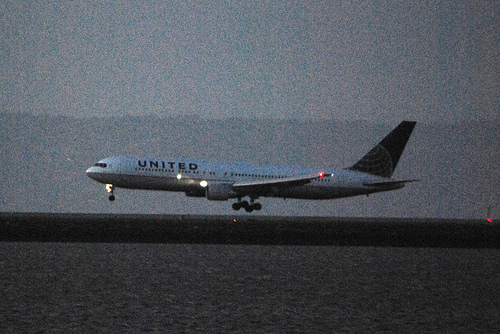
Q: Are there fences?
A: No, there are no fences.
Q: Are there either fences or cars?
A: No, there are no fences or cars.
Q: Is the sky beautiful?
A: Yes, the sky is beautiful.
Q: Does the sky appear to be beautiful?
A: Yes, the sky is beautiful.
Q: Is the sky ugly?
A: No, the sky is beautiful.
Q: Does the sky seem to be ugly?
A: No, the sky is beautiful.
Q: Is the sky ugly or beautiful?
A: The sky is beautiful.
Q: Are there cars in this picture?
A: No, there are no cars.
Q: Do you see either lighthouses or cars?
A: No, there are no cars or lighthouses.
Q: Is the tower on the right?
A: Yes, the tower is on the right of the image.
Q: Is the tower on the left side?
A: No, the tower is on the right of the image.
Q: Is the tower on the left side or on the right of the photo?
A: The tower is on the right of the image.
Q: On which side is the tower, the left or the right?
A: The tower is on the right of the image.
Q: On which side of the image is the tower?
A: The tower is on the right of the image.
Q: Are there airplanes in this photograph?
A: Yes, there is an airplane.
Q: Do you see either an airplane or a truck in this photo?
A: Yes, there is an airplane.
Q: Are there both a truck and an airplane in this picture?
A: No, there is an airplane but no trucks.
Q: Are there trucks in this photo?
A: No, there are no trucks.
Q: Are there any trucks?
A: No, there are no trucks.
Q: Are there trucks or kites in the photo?
A: No, there are no trucks or kites.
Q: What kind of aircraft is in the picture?
A: The aircraft is an airplane.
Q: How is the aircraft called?
A: The aircraft is an airplane.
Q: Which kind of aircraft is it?
A: The aircraft is an airplane.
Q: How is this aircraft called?
A: This is an airplane.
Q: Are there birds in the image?
A: No, there are no birds.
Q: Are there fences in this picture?
A: No, there are no fences.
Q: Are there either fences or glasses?
A: No, there are no fences or glasses.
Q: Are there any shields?
A: No, there are no shields.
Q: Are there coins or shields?
A: No, there are no shields or coins.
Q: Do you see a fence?
A: No, there are no fences.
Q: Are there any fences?
A: No, there are no fences.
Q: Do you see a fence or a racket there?
A: No, there are no fences or rackets.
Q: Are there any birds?
A: No, there are no birds.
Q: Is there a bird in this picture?
A: No, there are no birds.